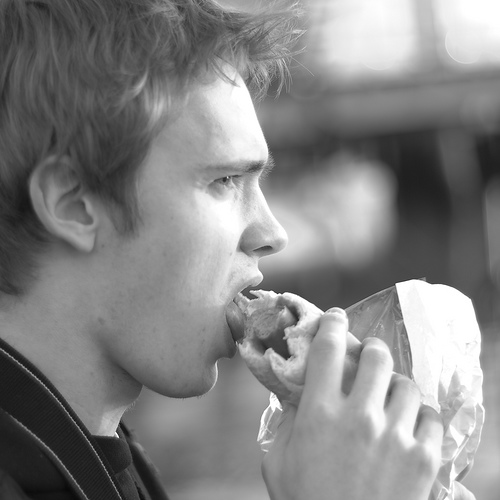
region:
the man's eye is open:
[206, 166, 243, 198]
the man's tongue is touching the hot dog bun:
[222, 298, 247, 349]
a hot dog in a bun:
[232, 292, 368, 399]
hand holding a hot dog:
[261, 307, 439, 498]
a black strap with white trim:
[0, 342, 125, 497]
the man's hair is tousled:
[4, 2, 309, 299]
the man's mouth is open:
[218, 267, 270, 367]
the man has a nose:
[238, 178, 290, 261]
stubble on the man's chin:
[172, 388, 214, 404]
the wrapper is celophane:
[325, 272, 487, 498]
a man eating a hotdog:
[8, 8, 399, 410]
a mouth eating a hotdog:
[211, 261, 311, 369]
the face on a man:
[138, 86, 285, 383]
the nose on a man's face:
[243, 198, 288, 260]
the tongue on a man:
[214, 296, 249, 346]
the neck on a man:
[18, 357, 144, 451]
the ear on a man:
[16, 143, 102, 253]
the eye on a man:
[200, 160, 248, 198]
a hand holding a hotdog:
[249, 284, 440, 484]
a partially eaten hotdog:
[250, 287, 342, 409]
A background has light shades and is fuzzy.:
[124, 5, 499, 497]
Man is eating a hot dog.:
[1, 0, 446, 499]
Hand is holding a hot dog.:
[236, 291, 446, 497]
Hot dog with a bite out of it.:
[234, 290, 362, 390]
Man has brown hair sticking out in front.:
[0, 1, 307, 303]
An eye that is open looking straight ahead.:
[213, 172, 239, 185]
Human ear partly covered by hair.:
[27, 150, 96, 256]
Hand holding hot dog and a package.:
[241, 277, 484, 498]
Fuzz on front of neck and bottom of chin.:
[116, 389, 218, 414]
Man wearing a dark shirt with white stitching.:
[1, 338, 172, 498]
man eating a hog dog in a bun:
[181, 131, 410, 423]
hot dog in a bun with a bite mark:
[245, 292, 307, 392]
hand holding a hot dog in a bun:
[253, 291, 436, 499]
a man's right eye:
[210, 172, 242, 201]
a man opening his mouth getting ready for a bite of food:
[222, 287, 254, 350]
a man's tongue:
[228, 304, 247, 343]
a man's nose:
[250, 203, 289, 255]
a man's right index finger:
[305, 308, 345, 412]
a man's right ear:
[31, 153, 96, 253]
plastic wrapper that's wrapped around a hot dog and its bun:
[361, 282, 478, 367]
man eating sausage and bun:
[4, 3, 419, 433]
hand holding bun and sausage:
[246, 282, 468, 497]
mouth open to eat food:
[208, 263, 373, 408]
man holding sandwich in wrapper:
[246, 278, 492, 490]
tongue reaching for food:
[221, 281, 335, 394]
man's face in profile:
[5, 6, 284, 398]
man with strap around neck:
[5, 4, 268, 491]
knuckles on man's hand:
[273, 365, 443, 475]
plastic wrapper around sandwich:
[236, 274, 491, 498]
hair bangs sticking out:
[169, 10, 326, 125]